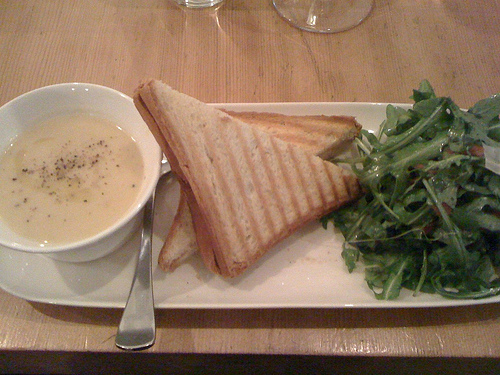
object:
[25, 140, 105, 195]
pepper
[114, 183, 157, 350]
handle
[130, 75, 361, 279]
sandwich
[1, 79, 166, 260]
bowl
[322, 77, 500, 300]
salad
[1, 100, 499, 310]
plate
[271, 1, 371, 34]
glass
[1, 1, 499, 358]
table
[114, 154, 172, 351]
spoon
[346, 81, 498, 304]
lettuce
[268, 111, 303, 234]
lines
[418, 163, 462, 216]
tomatoes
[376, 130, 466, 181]
leaves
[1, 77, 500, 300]
food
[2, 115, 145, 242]
soup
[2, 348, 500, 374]
edge